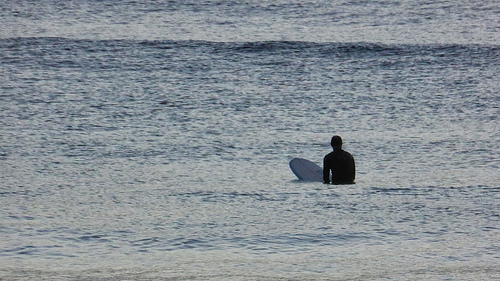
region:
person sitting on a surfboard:
[275, 125, 361, 193]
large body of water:
[2, 1, 498, 280]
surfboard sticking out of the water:
[289, 151, 318, 183]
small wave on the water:
[12, 21, 499, 65]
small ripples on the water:
[30, 68, 165, 121]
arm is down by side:
[314, 153, 334, 183]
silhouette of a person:
[311, 123, 367, 193]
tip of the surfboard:
[284, 150, 312, 176]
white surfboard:
[282, 150, 324, 186]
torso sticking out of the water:
[317, 132, 360, 189]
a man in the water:
[288, 130, 360, 200]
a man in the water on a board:
[285, 130, 352, 200]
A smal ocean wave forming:
[65, 10, 480, 110]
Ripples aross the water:
[55, 65, 285, 200]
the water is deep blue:
[35, 130, 185, 240]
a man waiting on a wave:
[281, 117, 373, 203]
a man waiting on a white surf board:
[287, 132, 357, 188]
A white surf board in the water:
[280, 155, 320, 187]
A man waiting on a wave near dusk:
[285, 116, 369, 208]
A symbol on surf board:
[290, 158, 323, 180]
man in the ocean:
[324, 124, 363, 189]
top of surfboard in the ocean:
[283, 150, 324, 185]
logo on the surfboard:
[316, 165, 323, 180]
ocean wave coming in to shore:
[22, 28, 482, 72]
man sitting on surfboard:
[278, 134, 371, 203]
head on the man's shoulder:
[327, 135, 347, 146]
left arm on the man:
[322, 151, 331, 185]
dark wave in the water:
[160, 93, 187, 113]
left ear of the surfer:
[326, 140, 333, 145]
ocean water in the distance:
[96, 7, 441, 104]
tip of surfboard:
[283, 153, 334, 184]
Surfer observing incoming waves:
[316, 131, 361, 188]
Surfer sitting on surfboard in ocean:
[285, 130, 360, 192]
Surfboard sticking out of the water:
[283, 150, 326, 190]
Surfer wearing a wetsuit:
[318, 132, 360, 187]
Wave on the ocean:
[3, 30, 495, 74]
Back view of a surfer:
[317, 131, 359, 187]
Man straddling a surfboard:
[284, 130, 362, 190]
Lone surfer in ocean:
[3, 41, 493, 259]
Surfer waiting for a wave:
[285, 130, 362, 187]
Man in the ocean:
[321, 135, 355, 184]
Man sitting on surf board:
[322, 134, 356, 184]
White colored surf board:
[287, 156, 336, 182]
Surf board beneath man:
[287, 158, 344, 182]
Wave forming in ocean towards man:
[2, 36, 483, 69]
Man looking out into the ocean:
[324, 134, 356, 187]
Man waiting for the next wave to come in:
[324, 134, 357, 184]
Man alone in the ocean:
[323, 134, 357, 184]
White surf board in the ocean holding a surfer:
[289, 157, 347, 182]